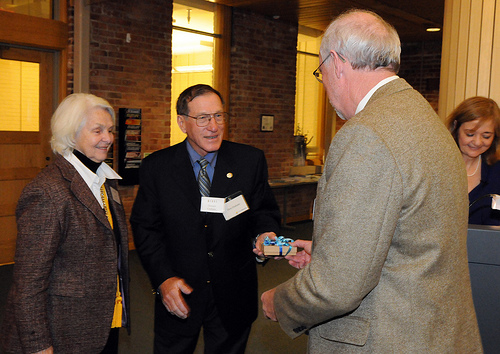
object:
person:
[128, 84, 276, 354]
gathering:
[0, 0, 498, 353]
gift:
[262, 236, 298, 256]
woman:
[0, 92, 130, 354]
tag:
[200, 196, 226, 213]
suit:
[129, 136, 283, 353]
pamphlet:
[125, 114, 141, 118]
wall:
[69, 0, 442, 253]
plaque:
[260, 115, 274, 132]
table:
[270, 181, 315, 231]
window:
[170, 1, 229, 147]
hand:
[253, 232, 277, 258]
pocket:
[317, 319, 370, 354]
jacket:
[275, 76, 483, 353]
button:
[226, 173, 233, 178]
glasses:
[313, 51, 346, 75]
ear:
[330, 50, 341, 79]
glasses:
[179, 112, 227, 127]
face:
[187, 95, 226, 151]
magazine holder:
[119, 105, 141, 171]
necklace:
[461, 155, 482, 176]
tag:
[492, 193, 500, 210]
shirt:
[468, 155, 500, 225]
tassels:
[100, 185, 123, 328]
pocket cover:
[235, 257, 255, 273]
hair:
[49, 92, 116, 155]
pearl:
[470, 175, 473, 177]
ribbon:
[263, 235, 295, 256]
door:
[0, 39, 63, 269]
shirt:
[185, 142, 219, 197]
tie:
[197, 158, 211, 197]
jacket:
[2, 153, 132, 353]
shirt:
[57, 146, 124, 209]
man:
[258, 8, 486, 353]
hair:
[443, 96, 500, 165]